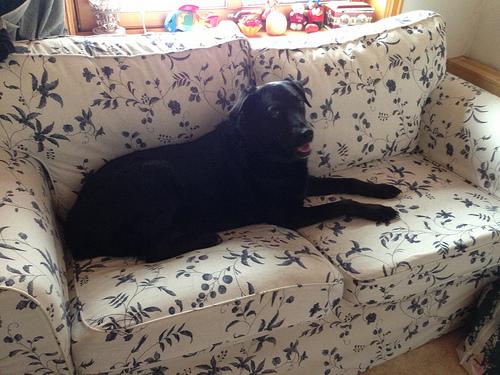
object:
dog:
[58, 77, 405, 268]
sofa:
[3, 10, 498, 373]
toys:
[288, 1, 306, 36]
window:
[65, 2, 390, 29]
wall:
[404, 0, 500, 83]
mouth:
[292, 136, 314, 161]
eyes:
[268, 105, 286, 123]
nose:
[299, 126, 314, 143]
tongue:
[299, 144, 311, 154]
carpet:
[375, 326, 471, 374]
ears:
[226, 85, 256, 126]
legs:
[296, 175, 403, 200]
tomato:
[303, 21, 320, 34]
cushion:
[252, 9, 446, 178]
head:
[229, 78, 315, 162]